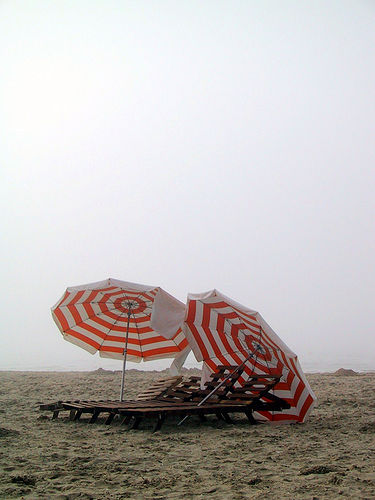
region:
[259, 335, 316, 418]
the umbrella is leaning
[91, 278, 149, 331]
the umbrella is standing up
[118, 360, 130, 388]
the pole is gray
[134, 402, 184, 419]
the chair is brown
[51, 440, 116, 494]
the sand is clupmy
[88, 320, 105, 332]
the line on the umbrella is white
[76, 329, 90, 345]
the line on the umbrella is orange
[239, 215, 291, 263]
the sky is very hazy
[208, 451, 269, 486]
the sand is a light tan color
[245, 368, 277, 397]
the chair is leaning backwards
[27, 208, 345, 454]
Beach side with umbrellas and lounge cahirs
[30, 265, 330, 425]
Two large beach umbrellas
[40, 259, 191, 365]
Beach umbrella with flap collapsed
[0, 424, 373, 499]
Dark grey trampled sand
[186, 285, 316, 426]
Beach umbrella with orange and white stripes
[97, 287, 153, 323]
Metal canopy for umbrella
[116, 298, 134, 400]
Metal umbrella center post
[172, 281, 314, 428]
Unsupported umbrella lying in sand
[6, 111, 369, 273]
Light grey overcast skies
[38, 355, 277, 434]
Four wooden lounge chairs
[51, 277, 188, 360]
The umbrellas are round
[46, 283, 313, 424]
The umbrellas have stripes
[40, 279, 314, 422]
The stripes are red and white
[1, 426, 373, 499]
The sand is brown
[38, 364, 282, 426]
The chairs are brown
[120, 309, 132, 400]
The pole is silver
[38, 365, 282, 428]
There are four chairs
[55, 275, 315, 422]
The umbrellas have red and white stripes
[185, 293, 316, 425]
The umbrella is touching the ground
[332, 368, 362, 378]
The mound of dirt is in the distance.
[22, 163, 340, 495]
umbrellas on a beach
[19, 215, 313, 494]
two umbrellas on a beach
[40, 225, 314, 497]
red and white umbrellas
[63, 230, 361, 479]
red and white umbrellas on the beach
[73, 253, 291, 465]
umbrellas on the sand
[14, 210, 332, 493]
large umbrellas on the beach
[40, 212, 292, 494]
large umbrellas on the sand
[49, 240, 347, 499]
a beach with umbrellas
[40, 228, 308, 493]
chairs on the beach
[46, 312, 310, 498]
wooden chairs on a beach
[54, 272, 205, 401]
the umbrella is stripes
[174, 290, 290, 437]
the umbrella is stripes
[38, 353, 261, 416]
the bench is brown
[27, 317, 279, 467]
benches under the umbrellas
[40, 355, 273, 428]
benches under the umbrellas